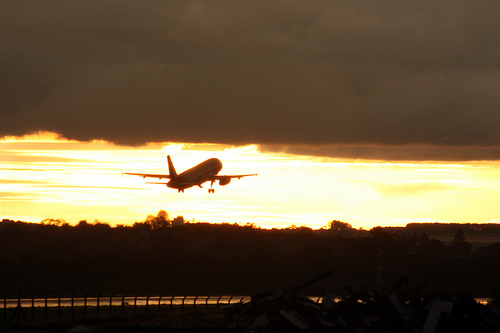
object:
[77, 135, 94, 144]
clouds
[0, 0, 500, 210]
sky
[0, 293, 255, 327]
fence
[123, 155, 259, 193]
plane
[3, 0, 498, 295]
air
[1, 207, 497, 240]
horizon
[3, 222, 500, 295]
shrubbery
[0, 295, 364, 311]
rubway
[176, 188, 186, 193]
gear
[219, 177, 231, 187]
engine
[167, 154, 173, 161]
tail end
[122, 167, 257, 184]
wingspan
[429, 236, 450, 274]
trees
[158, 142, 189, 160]
sun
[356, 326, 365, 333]
rubble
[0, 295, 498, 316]
landing strip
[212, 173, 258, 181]
wing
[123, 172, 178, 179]
wing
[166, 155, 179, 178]
tail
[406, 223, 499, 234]
train